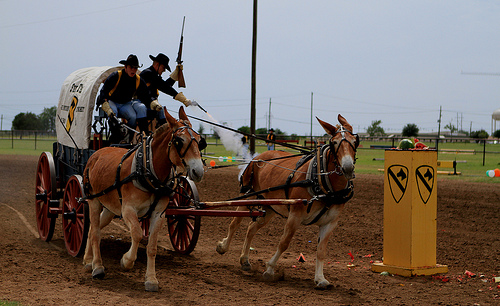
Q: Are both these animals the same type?
A: Yes, all the animals are horses.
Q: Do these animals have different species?
A: No, all the animals are horses.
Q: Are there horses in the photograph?
A: Yes, there is a horse.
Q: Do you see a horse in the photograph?
A: Yes, there is a horse.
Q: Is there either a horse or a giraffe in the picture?
A: Yes, there is a horse.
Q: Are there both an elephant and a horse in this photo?
A: No, there is a horse but no elephants.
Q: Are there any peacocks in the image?
A: No, there are no peacocks.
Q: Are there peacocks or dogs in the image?
A: No, there are no peacocks or dogs.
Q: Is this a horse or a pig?
A: This is a horse.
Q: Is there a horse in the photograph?
A: Yes, there is a horse.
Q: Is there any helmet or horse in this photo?
A: Yes, there is a horse.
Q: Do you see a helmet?
A: No, there are no helmets.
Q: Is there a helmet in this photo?
A: No, there are no helmets.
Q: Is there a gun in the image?
A: Yes, there is a gun.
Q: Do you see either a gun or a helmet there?
A: Yes, there is a gun.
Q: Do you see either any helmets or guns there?
A: Yes, there is a gun.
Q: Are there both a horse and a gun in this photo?
A: Yes, there are both a gun and a horse.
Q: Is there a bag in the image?
A: No, there are no bags.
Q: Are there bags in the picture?
A: No, there are no bags.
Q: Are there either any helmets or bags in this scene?
A: No, there are no bags or helmets.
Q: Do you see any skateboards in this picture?
A: No, there are no skateboards.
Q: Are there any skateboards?
A: No, there are no skateboards.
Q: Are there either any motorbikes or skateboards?
A: No, there are no skateboards or motorbikes.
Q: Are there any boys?
A: No, there are no boys.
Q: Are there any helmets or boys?
A: No, there are no boys or helmets.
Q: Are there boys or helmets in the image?
A: No, there are no boys or helmets.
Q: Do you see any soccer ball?
A: No, there are no soccer balls.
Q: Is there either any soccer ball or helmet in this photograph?
A: No, there are no soccer balls or helmets.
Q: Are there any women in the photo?
A: No, there are no women.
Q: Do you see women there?
A: No, there are no women.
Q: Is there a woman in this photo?
A: No, there are no women.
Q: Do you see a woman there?
A: No, there are no women.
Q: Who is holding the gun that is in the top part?
A: The man is holding the gun.